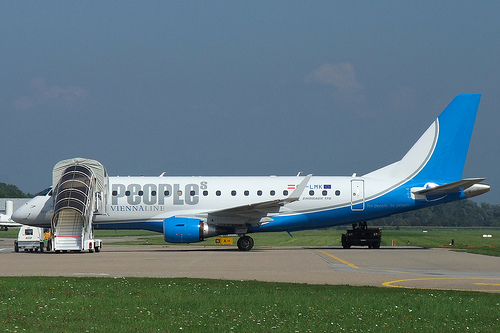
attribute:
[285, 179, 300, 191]
flag — Australian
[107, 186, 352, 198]
windows — 76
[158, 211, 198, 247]
engine — blue, jet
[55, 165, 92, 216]
stairs — covered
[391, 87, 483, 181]
tail — blue, white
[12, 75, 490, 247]
plane — white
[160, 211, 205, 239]
engine — blue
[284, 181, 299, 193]
flag — red, white, striped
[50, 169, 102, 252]
staircase — mobile, covered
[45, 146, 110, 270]
staircase — mobile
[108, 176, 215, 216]
peoples viennaline — airplane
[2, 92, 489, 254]
airplane — blue, white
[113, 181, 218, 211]
words — big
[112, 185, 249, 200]
seats — passenger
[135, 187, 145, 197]
window — round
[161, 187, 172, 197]
window — round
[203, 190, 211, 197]
window — round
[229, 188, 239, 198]
window — round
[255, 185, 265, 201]
window — round